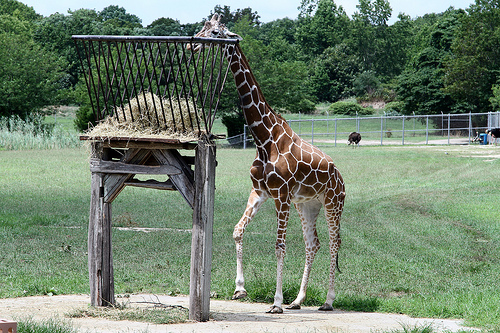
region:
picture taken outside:
[19, 18, 401, 290]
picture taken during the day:
[23, 28, 488, 290]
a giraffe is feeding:
[51, 5, 379, 146]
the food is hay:
[65, 30, 205, 135]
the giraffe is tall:
[245, 76, 392, 309]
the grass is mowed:
[378, 186, 438, 279]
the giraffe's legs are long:
[227, 127, 358, 293]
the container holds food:
[60, 18, 267, 180]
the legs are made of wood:
[85, 128, 246, 319]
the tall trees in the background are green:
[262, 20, 422, 115]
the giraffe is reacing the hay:
[193, 13, 371, 323]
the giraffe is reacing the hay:
[73, 4, 391, 238]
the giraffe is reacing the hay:
[89, 12, 289, 190]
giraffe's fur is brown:
[222, 29, 376, 297]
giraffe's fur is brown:
[170, 12, 320, 217]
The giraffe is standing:
[187, 16, 346, 316]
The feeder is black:
[75, 27, 234, 147]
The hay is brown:
[81, 84, 208, 151]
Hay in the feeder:
[72, 34, 235, 146]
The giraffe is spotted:
[190, 12, 347, 313]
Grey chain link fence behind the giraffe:
[250, 103, 491, 147]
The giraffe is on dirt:
[193, 15, 349, 322]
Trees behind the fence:
[1, 4, 493, 120]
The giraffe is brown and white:
[196, 13, 346, 313]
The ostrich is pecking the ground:
[344, 132, 363, 147]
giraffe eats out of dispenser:
[161, 23, 373, 295]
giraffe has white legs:
[217, 201, 347, 324]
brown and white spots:
[233, 70, 350, 205]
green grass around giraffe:
[352, 150, 444, 303]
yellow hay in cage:
[99, 89, 209, 142]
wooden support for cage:
[56, 143, 211, 328]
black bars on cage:
[72, 16, 219, 135]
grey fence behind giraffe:
[261, 105, 488, 151]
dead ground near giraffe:
[22, 291, 397, 332]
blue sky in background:
[152, 0, 337, 14]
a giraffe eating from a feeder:
[167, 8, 366, 308]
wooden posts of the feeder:
[78, 146, 213, 310]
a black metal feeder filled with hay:
[61, 21, 223, 142]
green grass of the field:
[369, 174, 499, 320]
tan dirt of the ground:
[241, 303, 312, 331]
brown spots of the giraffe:
[266, 128, 317, 191]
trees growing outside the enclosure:
[283, 21, 490, 93]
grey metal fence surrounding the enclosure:
[398, 105, 470, 145]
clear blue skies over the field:
[264, 0, 287, 16]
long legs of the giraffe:
[230, 190, 360, 316]